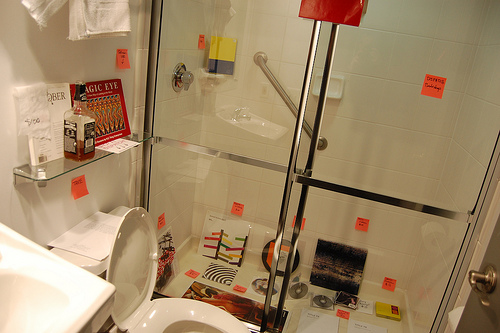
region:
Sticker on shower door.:
[421, 71, 448, 99]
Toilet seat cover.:
[108, 208, 155, 320]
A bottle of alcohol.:
[63, 82, 95, 159]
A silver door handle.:
[467, 266, 496, 312]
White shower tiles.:
[362, 110, 458, 180]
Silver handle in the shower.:
[253, 48, 328, 158]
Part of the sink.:
[6, 273, 95, 330]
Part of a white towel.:
[68, 2, 130, 37]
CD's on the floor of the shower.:
[288, 279, 333, 317]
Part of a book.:
[93, 78, 130, 143]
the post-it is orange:
[61, 172, 101, 202]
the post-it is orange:
[376, 271, 403, 301]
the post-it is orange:
[338, 216, 378, 236]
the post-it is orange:
[416, 70, 482, 117]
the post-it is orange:
[152, 204, 177, 231]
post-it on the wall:
[69, 171, 96, 196]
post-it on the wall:
[221, 189, 251, 214]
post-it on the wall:
[351, 212, 378, 239]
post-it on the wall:
[369, 261, 418, 303]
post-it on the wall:
[414, 71, 451, 102]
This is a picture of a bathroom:
[1, 0, 446, 291]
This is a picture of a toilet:
[101, 225, 224, 331]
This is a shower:
[184, 60, 435, 328]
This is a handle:
[212, 170, 355, 307]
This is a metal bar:
[250, 45, 383, 202]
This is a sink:
[14, 257, 105, 320]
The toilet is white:
[86, 220, 176, 313]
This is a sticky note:
[417, 45, 455, 147]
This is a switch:
[174, 67, 236, 162]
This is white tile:
[379, 36, 422, 196]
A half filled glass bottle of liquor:
[62, 83, 96, 162]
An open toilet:
[104, 206, 249, 331]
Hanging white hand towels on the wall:
[10, 0, 130, 42]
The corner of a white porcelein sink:
[0, 219, 118, 331]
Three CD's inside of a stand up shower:
[248, 274, 335, 309]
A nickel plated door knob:
[463, 264, 498, 326]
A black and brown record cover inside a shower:
[310, 236, 367, 294]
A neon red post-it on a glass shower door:
[420, 73, 447, 99]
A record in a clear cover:
[258, 232, 304, 280]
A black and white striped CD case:
[202, 260, 236, 285]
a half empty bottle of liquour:
[60, 78, 97, 163]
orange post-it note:
[419, 71, 449, 100]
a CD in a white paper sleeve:
[310, 292, 336, 311]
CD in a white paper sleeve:
[285, 278, 312, 301]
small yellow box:
[372, 298, 402, 323]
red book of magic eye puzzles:
[68, 75, 132, 153]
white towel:
[64, 0, 134, 41]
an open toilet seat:
[102, 202, 254, 332]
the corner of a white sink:
[1, 220, 118, 332]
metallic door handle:
[465, 262, 496, 310]